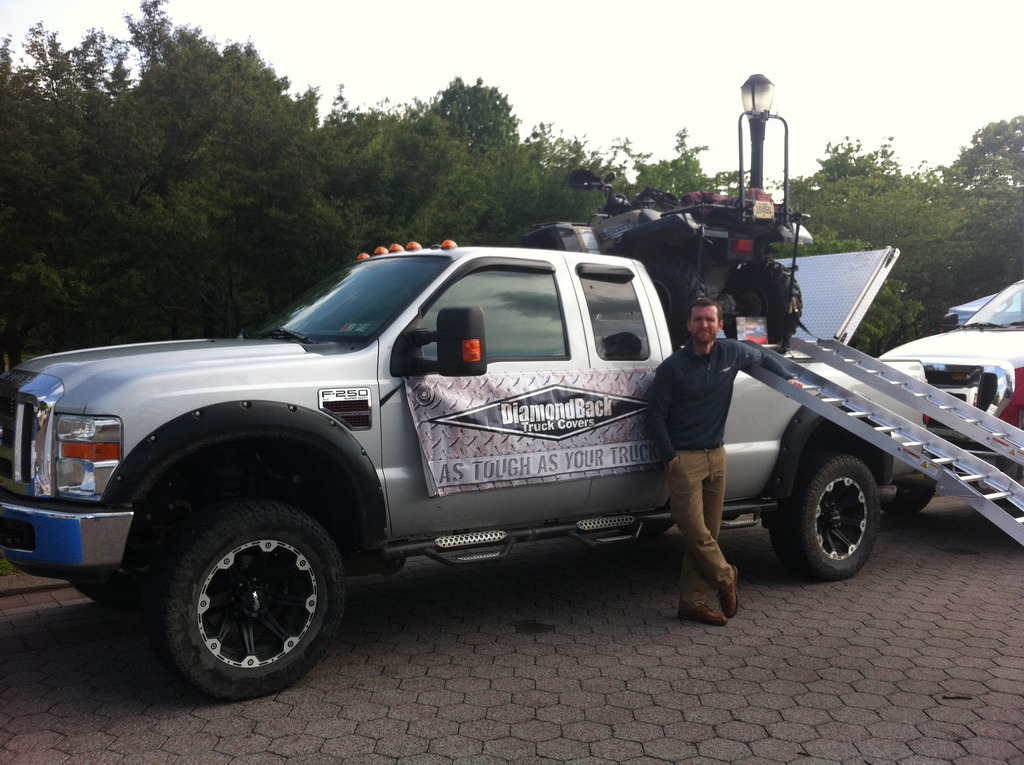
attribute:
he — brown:
[645, 309, 751, 621]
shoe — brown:
[714, 558, 743, 621]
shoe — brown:
[674, 592, 726, 627]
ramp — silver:
[787, 331, 1021, 476]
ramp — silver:
[735, 346, 1021, 548]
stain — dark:
[500, 605, 561, 640]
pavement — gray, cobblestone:
[3, 489, 1021, 758]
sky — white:
[0, 3, 1024, 205]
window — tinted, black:
[575, 264, 651, 364]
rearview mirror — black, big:
[387, 307, 489, 381]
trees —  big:
[766, 121, 1022, 359]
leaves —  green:
[874, 139, 900, 179]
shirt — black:
[645, 338, 784, 457]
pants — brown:
[663, 444, 741, 615]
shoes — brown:
[673, 560, 745, 628]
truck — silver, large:
[10, 225, 911, 707]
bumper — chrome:
[0, 487, 143, 580]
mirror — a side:
[386, 301, 490, 381]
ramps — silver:
[754, 335, 992, 465]